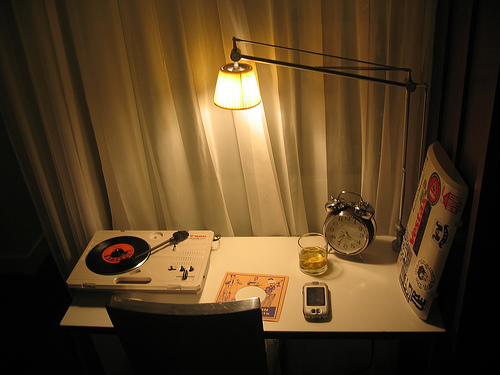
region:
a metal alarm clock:
[322, 194, 377, 258]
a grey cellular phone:
[302, 279, 331, 318]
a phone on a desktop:
[295, 278, 344, 323]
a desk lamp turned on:
[212, 32, 413, 247]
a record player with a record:
[80, 221, 212, 294]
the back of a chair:
[107, 289, 272, 340]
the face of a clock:
[330, 218, 367, 254]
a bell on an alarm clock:
[351, 198, 375, 218]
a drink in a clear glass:
[296, 236, 328, 273]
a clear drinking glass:
[296, 235, 331, 272]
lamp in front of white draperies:
[10, 6, 485, 221]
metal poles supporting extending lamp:
[211, 26, 431, 251]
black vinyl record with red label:
[60, 215, 212, 306]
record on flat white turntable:
[62, 220, 212, 300]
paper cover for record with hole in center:
[211, 262, 283, 318]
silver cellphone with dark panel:
[300, 276, 330, 321]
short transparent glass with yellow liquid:
[292, 226, 327, 271]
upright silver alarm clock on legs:
[316, 185, 376, 260]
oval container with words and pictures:
[391, 130, 466, 325]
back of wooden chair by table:
[100, 295, 270, 362]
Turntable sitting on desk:
[65, 217, 213, 297]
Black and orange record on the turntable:
[82, 227, 158, 277]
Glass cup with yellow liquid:
[290, 227, 338, 274]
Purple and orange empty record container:
[212, 259, 287, 323]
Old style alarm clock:
[315, 181, 381, 270]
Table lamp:
[210, 35, 425, 255]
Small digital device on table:
[295, 278, 333, 328]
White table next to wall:
[52, 205, 460, 342]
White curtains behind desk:
[17, 8, 489, 288]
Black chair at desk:
[97, 288, 284, 371]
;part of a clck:
[322, 205, 332, 220]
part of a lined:
[233, 116, 273, 228]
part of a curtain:
[286, 176, 300, 207]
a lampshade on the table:
[210, 31, 430, 263]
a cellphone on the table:
[300, 278, 333, 323]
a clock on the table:
[320, 185, 377, 262]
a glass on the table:
[294, 230, 331, 276]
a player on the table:
[61, 225, 220, 302]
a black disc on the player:
[82, 233, 154, 277]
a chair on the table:
[102, 294, 279, 374]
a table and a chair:
[51, 225, 456, 370]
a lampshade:
[210, 60, 263, 111]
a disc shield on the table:
[213, 270, 289, 322]